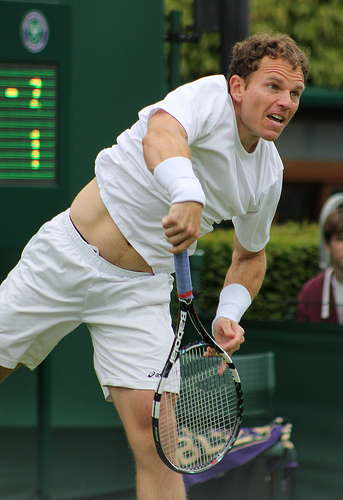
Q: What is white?
A: Shirt.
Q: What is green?
A: Sign.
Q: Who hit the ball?
A: Man.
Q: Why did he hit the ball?
A: Playing.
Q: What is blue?
A: Handle.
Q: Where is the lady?
A: To the right of the player.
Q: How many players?
A: One.